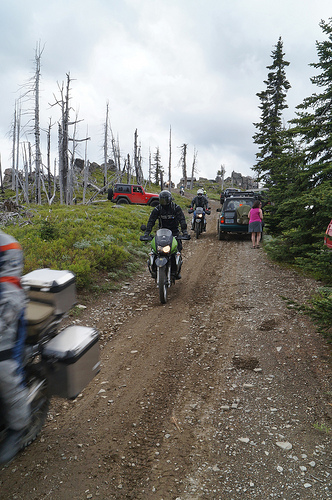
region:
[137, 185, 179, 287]
man riding a bike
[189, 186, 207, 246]
man riding a bike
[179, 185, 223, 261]
man riding a bike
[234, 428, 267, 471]
small stone on the ground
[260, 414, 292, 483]
small stone on the ground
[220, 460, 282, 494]
small stone on the ground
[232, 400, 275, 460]
small stone on the ground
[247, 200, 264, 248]
A woman wearing casual clothes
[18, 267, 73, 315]
A container on the back of a vehicle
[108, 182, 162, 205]
A red vehicle outside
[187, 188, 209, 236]
A person driving a motor bike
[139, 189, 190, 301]
A person suited up driving a motor bike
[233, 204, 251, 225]
A spare tire on the back of a vehicle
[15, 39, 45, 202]
A tree without leaves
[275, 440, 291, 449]
A rock on the ground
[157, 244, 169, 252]
Headlights on a bike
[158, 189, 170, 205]
A helmet on someones head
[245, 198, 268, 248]
A woman wearing a pink shirt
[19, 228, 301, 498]
A dirt path by the grass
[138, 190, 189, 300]
A man riding a motorbike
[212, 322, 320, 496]
Rocks in the dirt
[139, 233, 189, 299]
A green motorbike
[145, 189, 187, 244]
A man wearing all black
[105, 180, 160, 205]
A parked red jeep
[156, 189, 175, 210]
A black motorcycle helmet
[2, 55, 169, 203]
Dead white trees in the grass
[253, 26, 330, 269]
Pine trees lining the path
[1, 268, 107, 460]
The motorcyle in the lead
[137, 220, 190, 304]
The black and green motorcycle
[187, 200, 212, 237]
The blue and black motorcycle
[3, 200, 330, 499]
The dirt road the vehicles are on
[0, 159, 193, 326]
Green bushes to the left of the road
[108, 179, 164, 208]
The red and black jeep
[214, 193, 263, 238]
The blue jeep on the road?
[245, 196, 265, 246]
The woman in the pink shirt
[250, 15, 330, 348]
The trees to the right of the road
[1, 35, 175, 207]
Dead white trees to road's left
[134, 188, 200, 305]
person a dirt bike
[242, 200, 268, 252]
lady standing on the dirt road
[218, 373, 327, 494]
rocks on the road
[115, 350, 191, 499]
tire track on the road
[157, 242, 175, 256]
headlight is on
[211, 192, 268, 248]
vehicle on the dirt road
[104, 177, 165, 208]
red and black jeep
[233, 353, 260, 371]
clump of dirt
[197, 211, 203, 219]
light on the front of the bike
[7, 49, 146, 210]
trees with no leaves on them